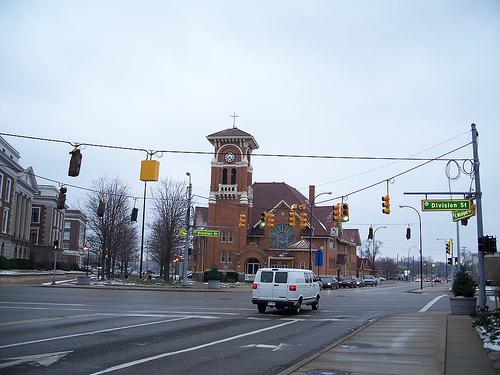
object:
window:
[269, 224, 294, 249]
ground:
[326, 164, 378, 185]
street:
[0, 273, 500, 375]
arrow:
[241, 342, 292, 351]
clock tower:
[205, 112, 260, 279]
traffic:
[321, 274, 378, 289]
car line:
[319, 275, 378, 289]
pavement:
[0, 274, 500, 374]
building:
[0, 136, 88, 272]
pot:
[450, 296, 478, 315]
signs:
[182, 230, 220, 238]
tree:
[71, 175, 139, 280]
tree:
[144, 176, 193, 282]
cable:
[0, 131, 473, 161]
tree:
[452, 265, 478, 297]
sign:
[315, 249, 324, 266]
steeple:
[203, 113, 259, 205]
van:
[252, 268, 321, 315]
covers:
[303, 369, 350, 375]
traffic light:
[382, 195, 391, 214]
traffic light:
[333, 202, 349, 222]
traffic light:
[300, 212, 308, 228]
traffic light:
[288, 211, 296, 228]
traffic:
[251, 268, 320, 315]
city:
[0, 113, 500, 375]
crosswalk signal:
[481, 235, 498, 255]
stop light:
[382, 196, 391, 215]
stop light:
[333, 202, 349, 222]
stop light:
[299, 204, 308, 229]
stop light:
[261, 212, 274, 228]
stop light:
[238, 214, 245, 228]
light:
[480, 235, 497, 255]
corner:
[392, 288, 492, 316]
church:
[192, 105, 361, 282]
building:
[203, 112, 362, 275]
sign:
[423, 199, 470, 210]